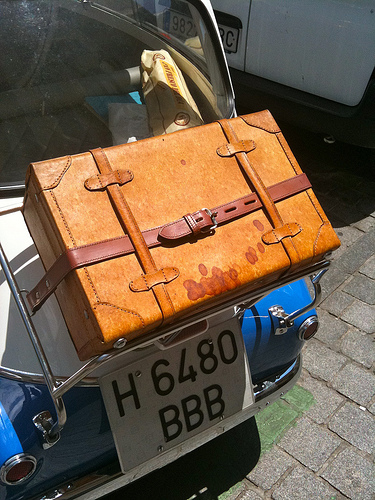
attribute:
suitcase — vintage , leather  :
[40, 128, 336, 297]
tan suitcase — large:
[26, 108, 347, 361]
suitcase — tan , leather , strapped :
[18, 108, 343, 360]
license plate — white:
[97, 316, 255, 473]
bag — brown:
[139, 46, 207, 138]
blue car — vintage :
[0, 1, 343, 499]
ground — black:
[319, 120, 336, 144]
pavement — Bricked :
[240, 195, 373, 497]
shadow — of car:
[284, 115, 374, 228]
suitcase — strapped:
[22, 139, 347, 317]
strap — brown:
[22, 161, 313, 309]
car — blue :
[152, 12, 361, 107]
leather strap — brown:
[26, 152, 313, 290]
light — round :
[4, 460, 36, 485]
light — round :
[301, 319, 318, 339]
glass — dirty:
[2, 1, 233, 184]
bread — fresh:
[137, 48, 204, 133]